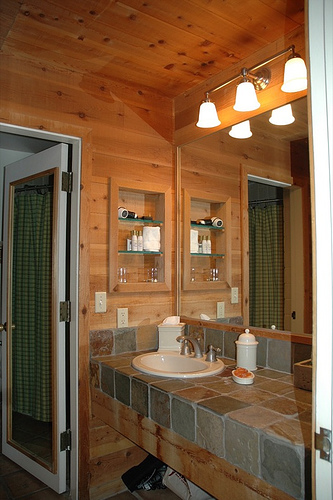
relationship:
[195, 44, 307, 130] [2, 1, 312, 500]
sconce in bathroom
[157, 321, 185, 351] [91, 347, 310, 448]
tissue holder in on counter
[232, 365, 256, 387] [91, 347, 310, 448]
soap dish on counter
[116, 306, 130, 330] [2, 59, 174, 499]
electrical outlet on wall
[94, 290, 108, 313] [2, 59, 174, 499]
light switch on wall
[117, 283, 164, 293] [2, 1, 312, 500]
shelf are in bathroom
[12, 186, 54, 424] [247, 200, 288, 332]
curtain has reflection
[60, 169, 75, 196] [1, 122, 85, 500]
hinge on door frame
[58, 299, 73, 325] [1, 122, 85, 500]
hinge on door frame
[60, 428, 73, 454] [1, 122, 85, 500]
hinge on door frame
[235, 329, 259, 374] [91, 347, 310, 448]
container on counter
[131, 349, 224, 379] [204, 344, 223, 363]
sink has right handle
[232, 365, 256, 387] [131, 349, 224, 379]
soap dish next to sink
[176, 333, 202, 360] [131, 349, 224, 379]
faucet on sink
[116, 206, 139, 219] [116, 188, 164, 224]
hair dryer on shelf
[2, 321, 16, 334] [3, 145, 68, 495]
door knob on door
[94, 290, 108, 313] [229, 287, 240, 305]
light switch has reflection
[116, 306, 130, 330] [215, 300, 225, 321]
electrical outlet has reflection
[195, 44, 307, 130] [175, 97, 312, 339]
sconce hangs over mirror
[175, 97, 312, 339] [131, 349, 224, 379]
mirror over sink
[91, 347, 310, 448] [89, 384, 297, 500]
counter has base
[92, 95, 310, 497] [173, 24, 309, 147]
vanity built into wall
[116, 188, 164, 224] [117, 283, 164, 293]
shelf in shelf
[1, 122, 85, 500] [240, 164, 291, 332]
door frame has reflection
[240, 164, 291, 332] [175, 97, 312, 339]
reflection in mirror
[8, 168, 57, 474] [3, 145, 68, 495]
mirror on door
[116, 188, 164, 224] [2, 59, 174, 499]
shelf in wall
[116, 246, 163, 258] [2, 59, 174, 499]
shelf in wall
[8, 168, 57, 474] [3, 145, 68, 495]
mirror hanging on door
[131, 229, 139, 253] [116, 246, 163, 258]
bottle on shelf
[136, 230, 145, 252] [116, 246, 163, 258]
bottle on shelf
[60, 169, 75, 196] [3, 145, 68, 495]
hinge on door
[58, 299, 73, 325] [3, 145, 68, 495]
hinge on door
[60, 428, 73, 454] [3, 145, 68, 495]
hinge on door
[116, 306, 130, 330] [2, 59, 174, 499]
electrical outlet in wall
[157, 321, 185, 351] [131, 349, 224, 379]
tissue holder on sink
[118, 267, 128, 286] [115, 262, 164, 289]
drinking glass sitting on shelf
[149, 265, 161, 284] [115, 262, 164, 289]
drinking glass sitting on shelf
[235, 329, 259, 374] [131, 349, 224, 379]
container sitting near sink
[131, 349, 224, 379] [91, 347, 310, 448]
sink in counter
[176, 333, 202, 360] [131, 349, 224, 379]
faucet for sink